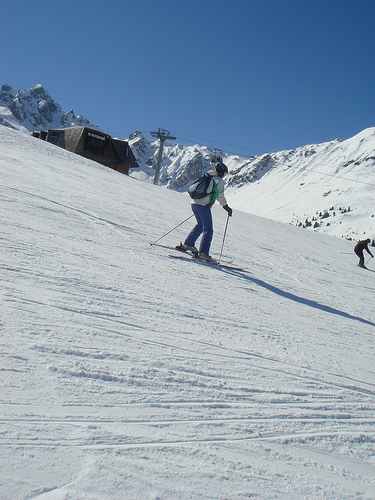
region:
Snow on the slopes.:
[127, 333, 204, 456]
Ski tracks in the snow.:
[115, 315, 203, 475]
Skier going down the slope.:
[175, 156, 270, 306]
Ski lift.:
[130, 113, 199, 190]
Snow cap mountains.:
[171, 113, 332, 208]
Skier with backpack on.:
[150, 131, 233, 278]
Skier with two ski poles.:
[143, 195, 275, 286]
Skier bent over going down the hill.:
[332, 212, 371, 292]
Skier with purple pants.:
[165, 135, 266, 307]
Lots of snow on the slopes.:
[102, 239, 283, 416]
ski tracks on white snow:
[94, 280, 276, 445]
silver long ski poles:
[162, 216, 185, 252]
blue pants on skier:
[186, 202, 238, 277]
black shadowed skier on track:
[345, 211, 373, 293]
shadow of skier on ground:
[247, 262, 369, 329]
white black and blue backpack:
[196, 166, 221, 232]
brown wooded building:
[48, 113, 145, 174]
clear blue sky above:
[111, 24, 308, 104]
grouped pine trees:
[297, 199, 357, 233]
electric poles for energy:
[133, 107, 178, 188]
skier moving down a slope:
[70, 93, 304, 300]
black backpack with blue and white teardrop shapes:
[150, 140, 252, 217]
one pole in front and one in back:
[126, 183, 261, 276]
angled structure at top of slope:
[30, 91, 144, 182]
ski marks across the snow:
[53, 367, 346, 450]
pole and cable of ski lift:
[135, 111, 345, 194]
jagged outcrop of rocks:
[10, 75, 87, 137]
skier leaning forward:
[315, 228, 368, 273]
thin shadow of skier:
[171, 225, 363, 337]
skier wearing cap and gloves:
[143, 131, 255, 299]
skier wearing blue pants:
[144, 156, 238, 272]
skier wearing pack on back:
[145, 161, 243, 267]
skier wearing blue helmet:
[148, 158, 240, 269]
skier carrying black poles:
[143, 156, 233, 270]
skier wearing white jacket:
[148, 160, 238, 270]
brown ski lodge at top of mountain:
[25, 117, 143, 182]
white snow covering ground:
[6, 75, 372, 489]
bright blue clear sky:
[3, 0, 369, 158]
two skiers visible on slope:
[138, 148, 374, 281]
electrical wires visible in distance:
[103, 121, 374, 202]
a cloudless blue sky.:
[4, 4, 374, 73]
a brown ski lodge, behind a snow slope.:
[29, 123, 140, 178]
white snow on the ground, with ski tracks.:
[1, 278, 373, 496]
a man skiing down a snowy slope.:
[148, 161, 239, 268]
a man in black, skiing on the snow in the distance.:
[338, 236, 373, 271]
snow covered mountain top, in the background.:
[4, 81, 86, 127]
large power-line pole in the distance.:
[154, 126, 174, 184]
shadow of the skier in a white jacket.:
[197, 268, 373, 323]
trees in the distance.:
[281, 199, 358, 227]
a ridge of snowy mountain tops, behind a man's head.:
[130, 129, 373, 176]